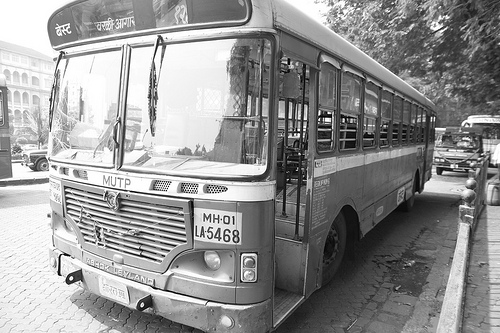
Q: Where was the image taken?
A: It was taken at the street.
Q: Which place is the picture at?
A: It is at the street.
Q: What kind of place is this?
A: It is a street.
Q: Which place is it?
A: It is a street.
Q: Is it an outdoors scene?
A: Yes, it is outdoors.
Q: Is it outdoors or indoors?
A: It is outdoors.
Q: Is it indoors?
A: No, it is outdoors.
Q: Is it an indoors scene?
A: No, it is outdoors.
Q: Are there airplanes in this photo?
A: No, there are no airplanes.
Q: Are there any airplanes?
A: No, there are no airplanes.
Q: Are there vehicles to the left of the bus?
A: Yes, there is a vehicle to the left of the bus.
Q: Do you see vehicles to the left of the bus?
A: Yes, there is a vehicle to the left of the bus.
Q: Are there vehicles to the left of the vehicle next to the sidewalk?
A: Yes, there is a vehicle to the left of the bus.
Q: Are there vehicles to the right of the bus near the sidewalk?
A: No, the vehicle is to the left of the bus.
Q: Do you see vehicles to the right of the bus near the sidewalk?
A: No, the vehicle is to the left of the bus.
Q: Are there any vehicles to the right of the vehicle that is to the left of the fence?
A: No, the vehicle is to the left of the bus.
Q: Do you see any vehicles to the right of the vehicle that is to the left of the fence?
A: No, the vehicle is to the left of the bus.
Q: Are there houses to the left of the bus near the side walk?
A: No, there is a vehicle to the left of the bus.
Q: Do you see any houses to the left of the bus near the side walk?
A: No, there is a vehicle to the left of the bus.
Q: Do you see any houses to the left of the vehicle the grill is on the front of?
A: No, there is a vehicle to the left of the bus.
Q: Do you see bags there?
A: No, there are no bags.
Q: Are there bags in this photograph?
A: No, there are no bags.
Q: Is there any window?
A: Yes, there is a window.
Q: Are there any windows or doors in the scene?
A: Yes, there is a window.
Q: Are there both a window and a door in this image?
A: Yes, there are both a window and a door.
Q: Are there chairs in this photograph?
A: No, there are no chairs.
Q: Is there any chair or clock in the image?
A: No, there are no chairs or clocks.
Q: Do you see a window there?
A: Yes, there is a window.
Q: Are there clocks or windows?
A: Yes, there is a window.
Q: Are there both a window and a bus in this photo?
A: Yes, there are both a window and a bus.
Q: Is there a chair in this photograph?
A: No, there are no chairs.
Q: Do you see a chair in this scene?
A: No, there are no chairs.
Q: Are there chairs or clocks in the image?
A: No, there are no chairs or clocks.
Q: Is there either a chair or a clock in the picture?
A: No, there are no chairs or clocks.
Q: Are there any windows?
A: Yes, there is a window.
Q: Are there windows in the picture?
A: Yes, there is a window.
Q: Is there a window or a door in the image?
A: Yes, there is a window.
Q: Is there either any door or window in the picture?
A: Yes, there is a window.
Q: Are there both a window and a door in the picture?
A: Yes, there are both a window and a door.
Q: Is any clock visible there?
A: No, there are no clocks.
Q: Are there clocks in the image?
A: No, there are no clocks.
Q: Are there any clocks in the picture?
A: No, there are no clocks.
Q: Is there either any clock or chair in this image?
A: No, there are no clocks or chairs.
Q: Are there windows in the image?
A: Yes, there is a window.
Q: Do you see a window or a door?
A: Yes, there is a window.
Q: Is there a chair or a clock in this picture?
A: No, there are no clocks or chairs.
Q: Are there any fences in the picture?
A: Yes, there is a fence.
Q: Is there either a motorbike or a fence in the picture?
A: Yes, there is a fence.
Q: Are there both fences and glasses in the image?
A: No, there is a fence but no glasses.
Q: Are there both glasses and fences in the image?
A: No, there is a fence but no glasses.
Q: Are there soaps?
A: No, there are no soaps.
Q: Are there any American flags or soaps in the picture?
A: No, there are no soaps or American flags.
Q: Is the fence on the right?
A: Yes, the fence is on the right of the image.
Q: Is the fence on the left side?
A: No, the fence is on the right of the image.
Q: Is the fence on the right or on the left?
A: The fence is on the right of the image.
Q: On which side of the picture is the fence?
A: The fence is on the right of the image.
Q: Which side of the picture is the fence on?
A: The fence is on the right of the image.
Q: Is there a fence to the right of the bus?
A: Yes, there is a fence to the right of the bus.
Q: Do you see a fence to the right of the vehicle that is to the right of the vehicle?
A: Yes, there is a fence to the right of the bus.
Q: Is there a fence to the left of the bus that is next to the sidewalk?
A: No, the fence is to the right of the bus.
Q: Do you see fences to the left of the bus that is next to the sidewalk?
A: No, the fence is to the right of the bus.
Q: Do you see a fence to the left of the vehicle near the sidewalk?
A: No, the fence is to the right of the bus.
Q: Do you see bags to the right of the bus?
A: No, there is a fence to the right of the bus.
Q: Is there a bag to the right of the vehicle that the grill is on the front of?
A: No, there is a fence to the right of the bus.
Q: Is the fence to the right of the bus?
A: Yes, the fence is to the right of the bus.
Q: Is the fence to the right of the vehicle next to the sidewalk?
A: Yes, the fence is to the right of the bus.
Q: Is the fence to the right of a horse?
A: No, the fence is to the right of the bus.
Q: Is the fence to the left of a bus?
A: No, the fence is to the right of a bus.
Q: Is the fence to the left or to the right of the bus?
A: The fence is to the right of the bus.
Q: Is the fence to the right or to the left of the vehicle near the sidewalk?
A: The fence is to the right of the bus.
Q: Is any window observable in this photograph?
A: Yes, there is a window.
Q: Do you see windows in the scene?
A: Yes, there is a window.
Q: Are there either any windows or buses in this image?
A: Yes, there is a window.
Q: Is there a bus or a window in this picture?
A: Yes, there is a window.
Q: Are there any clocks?
A: No, there are no clocks.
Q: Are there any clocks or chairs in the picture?
A: No, there are no clocks or chairs.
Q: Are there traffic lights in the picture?
A: No, there are no traffic lights.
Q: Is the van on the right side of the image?
A: Yes, the van is on the right of the image.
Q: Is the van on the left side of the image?
A: No, the van is on the right of the image.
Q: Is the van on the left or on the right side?
A: The van is on the right of the image.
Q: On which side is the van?
A: The van is on the right of the image.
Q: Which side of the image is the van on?
A: The van is on the right of the image.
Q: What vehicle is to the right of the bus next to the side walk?
A: The vehicle is a van.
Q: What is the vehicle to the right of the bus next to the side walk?
A: The vehicle is a van.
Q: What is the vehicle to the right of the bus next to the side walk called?
A: The vehicle is a van.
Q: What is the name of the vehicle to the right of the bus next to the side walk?
A: The vehicle is a van.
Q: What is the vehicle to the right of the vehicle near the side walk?
A: The vehicle is a van.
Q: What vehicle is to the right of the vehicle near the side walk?
A: The vehicle is a van.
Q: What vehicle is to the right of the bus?
A: The vehicle is a van.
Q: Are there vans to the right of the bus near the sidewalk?
A: Yes, there is a van to the right of the bus.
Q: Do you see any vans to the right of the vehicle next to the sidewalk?
A: Yes, there is a van to the right of the bus.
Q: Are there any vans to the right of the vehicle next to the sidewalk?
A: Yes, there is a van to the right of the bus.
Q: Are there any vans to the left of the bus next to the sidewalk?
A: No, the van is to the right of the bus.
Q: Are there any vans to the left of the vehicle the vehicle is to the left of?
A: No, the van is to the right of the bus.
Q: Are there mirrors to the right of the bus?
A: No, there is a van to the right of the bus.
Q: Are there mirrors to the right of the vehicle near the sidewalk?
A: No, there is a van to the right of the bus.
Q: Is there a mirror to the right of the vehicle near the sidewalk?
A: No, there is a van to the right of the bus.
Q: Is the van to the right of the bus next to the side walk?
A: Yes, the van is to the right of the bus.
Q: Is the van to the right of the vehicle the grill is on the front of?
A: Yes, the van is to the right of the bus.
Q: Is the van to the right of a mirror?
A: No, the van is to the right of the bus.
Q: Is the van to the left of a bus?
A: No, the van is to the right of a bus.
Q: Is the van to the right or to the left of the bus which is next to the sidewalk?
A: The van is to the right of the bus.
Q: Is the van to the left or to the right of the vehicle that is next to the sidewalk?
A: The van is to the right of the bus.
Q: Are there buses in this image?
A: Yes, there is a bus.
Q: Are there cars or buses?
A: Yes, there is a bus.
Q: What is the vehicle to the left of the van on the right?
A: The vehicle is a bus.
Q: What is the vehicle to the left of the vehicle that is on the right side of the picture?
A: The vehicle is a bus.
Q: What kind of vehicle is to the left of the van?
A: The vehicle is a bus.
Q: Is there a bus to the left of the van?
A: Yes, there is a bus to the left of the van.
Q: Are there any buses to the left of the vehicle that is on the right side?
A: Yes, there is a bus to the left of the van.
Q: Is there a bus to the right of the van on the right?
A: No, the bus is to the left of the van.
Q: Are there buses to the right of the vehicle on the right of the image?
A: No, the bus is to the left of the van.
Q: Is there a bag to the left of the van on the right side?
A: No, there is a bus to the left of the van.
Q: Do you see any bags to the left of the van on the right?
A: No, there is a bus to the left of the van.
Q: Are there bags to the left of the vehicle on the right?
A: No, there is a bus to the left of the van.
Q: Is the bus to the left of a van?
A: Yes, the bus is to the left of a van.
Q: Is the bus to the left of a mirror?
A: No, the bus is to the left of a van.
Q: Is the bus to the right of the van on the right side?
A: No, the bus is to the left of the van.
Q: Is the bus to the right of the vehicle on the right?
A: No, the bus is to the left of the van.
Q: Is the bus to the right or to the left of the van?
A: The bus is to the left of the van.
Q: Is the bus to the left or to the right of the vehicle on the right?
A: The bus is to the left of the van.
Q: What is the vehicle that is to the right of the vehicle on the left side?
A: The vehicle is a bus.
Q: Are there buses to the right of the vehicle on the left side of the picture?
A: Yes, there is a bus to the right of the vehicle.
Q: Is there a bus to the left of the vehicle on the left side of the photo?
A: No, the bus is to the right of the vehicle.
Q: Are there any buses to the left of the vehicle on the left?
A: No, the bus is to the right of the vehicle.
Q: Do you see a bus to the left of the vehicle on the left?
A: No, the bus is to the right of the vehicle.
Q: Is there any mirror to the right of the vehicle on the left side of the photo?
A: No, there is a bus to the right of the vehicle.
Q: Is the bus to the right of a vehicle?
A: Yes, the bus is to the right of a vehicle.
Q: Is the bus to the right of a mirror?
A: No, the bus is to the right of a vehicle.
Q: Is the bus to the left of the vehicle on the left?
A: No, the bus is to the right of the vehicle.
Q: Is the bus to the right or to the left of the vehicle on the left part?
A: The bus is to the right of the vehicle.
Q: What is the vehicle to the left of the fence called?
A: The vehicle is a bus.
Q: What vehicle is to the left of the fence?
A: The vehicle is a bus.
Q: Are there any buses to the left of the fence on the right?
A: Yes, there is a bus to the left of the fence.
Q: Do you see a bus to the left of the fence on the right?
A: Yes, there is a bus to the left of the fence.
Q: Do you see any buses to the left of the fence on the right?
A: Yes, there is a bus to the left of the fence.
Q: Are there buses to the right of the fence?
A: No, the bus is to the left of the fence.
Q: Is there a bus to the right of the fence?
A: No, the bus is to the left of the fence.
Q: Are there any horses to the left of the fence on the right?
A: No, there is a bus to the left of the fence.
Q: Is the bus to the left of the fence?
A: Yes, the bus is to the left of the fence.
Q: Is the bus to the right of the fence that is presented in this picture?
A: No, the bus is to the left of the fence.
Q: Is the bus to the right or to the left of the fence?
A: The bus is to the left of the fence.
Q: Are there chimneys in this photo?
A: No, there are no chimneys.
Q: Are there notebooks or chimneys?
A: No, there are no chimneys or notebooks.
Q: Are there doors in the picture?
A: Yes, there is a door.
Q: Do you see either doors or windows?
A: Yes, there is a door.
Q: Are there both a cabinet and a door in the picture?
A: No, there is a door but no cabinets.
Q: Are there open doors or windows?
A: Yes, there is an open door.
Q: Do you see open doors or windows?
A: Yes, there is an open door.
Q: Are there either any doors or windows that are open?
A: Yes, the door is open.